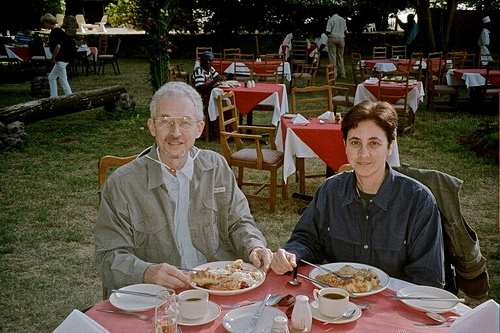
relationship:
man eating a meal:
[94, 81, 273, 299] [186, 258, 266, 294]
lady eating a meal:
[269, 101, 445, 288] [309, 262, 390, 297]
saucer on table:
[165, 300, 221, 326] [84, 263, 473, 332]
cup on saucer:
[170, 289, 208, 321] [165, 300, 221, 326]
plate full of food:
[188, 259, 266, 295] [190, 259, 261, 290]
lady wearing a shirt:
[269, 101, 445, 288] [282, 161, 446, 290]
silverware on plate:
[296, 256, 355, 288] [309, 262, 390, 297]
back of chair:
[217, 90, 245, 159] [216, 90, 288, 211]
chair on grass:
[216, 90, 288, 211] [0, 57, 499, 332]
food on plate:
[190, 259, 261, 290] [188, 259, 266, 295]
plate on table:
[188, 259, 266, 295] [84, 263, 473, 332]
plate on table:
[309, 262, 390, 297] [84, 263, 473, 332]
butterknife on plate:
[297, 271, 331, 289] [309, 262, 390, 297]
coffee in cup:
[323, 291, 345, 299] [313, 287, 350, 318]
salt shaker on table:
[290, 295, 312, 333] [84, 263, 473, 332]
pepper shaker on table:
[271, 317, 289, 332] [84, 263, 473, 332]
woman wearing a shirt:
[40, 13, 71, 96] [48, 26, 70, 61]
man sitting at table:
[94, 81, 273, 299] [84, 263, 473, 332]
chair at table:
[216, 90, 288, 211] [275, 115, 402, 214]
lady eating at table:
[269, 101, 445, 288] [84, 263, 473, 332]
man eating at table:
[94, 81, 273, 299] [84, 263, 473, 332]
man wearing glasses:
[94, 81, 273, 299] [149, 116, 199, 129]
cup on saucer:
[313, 287, 350, 318] [309, 299, 362, 325]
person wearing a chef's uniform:
[477, 16, 494, 66] [477, 15, 491, 67]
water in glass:
[156, 315, 176, 332] [155, 289, 177, 332]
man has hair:
[94, 81, 273, 299] [148, 82, 205, 123]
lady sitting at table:
[269, 101, 445, 288] [84, 263, 473, 332]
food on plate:
[315, 264, 380, 291] [309, 262, 390, 297]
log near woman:
[1, 85, 136, 144] [40, 13, 71, 96]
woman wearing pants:
[40, 13, 71, 96] [48, 61, 71, 98]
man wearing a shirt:
[94, 81, 273, 299] [156, 146, 207, 269]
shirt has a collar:
[156, 146, 207, 269] [156, 145, 194, 179]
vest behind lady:
[389, 162, 490, 300] [269, 101, 445, 288]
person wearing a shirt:
[190, 50, 233, 140] [191, 65, 219, 87]